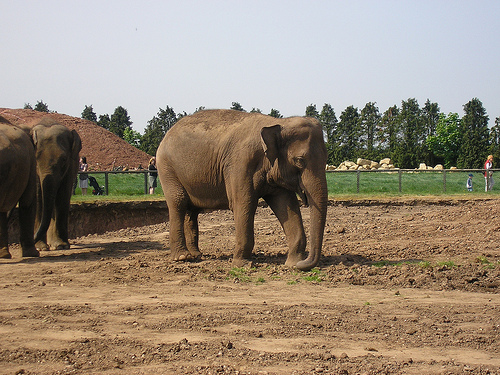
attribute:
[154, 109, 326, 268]
elephant — grey, standing, brown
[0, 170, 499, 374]
ground — brown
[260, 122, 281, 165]
ear — floppy, big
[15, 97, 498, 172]
trees — tall, green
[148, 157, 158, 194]
woman — standing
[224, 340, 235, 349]
rock — small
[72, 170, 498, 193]
grass — green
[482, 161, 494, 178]
jacket — red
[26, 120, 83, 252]
elephant — brown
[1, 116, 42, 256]
elephant — brown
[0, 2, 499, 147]
sky — blue